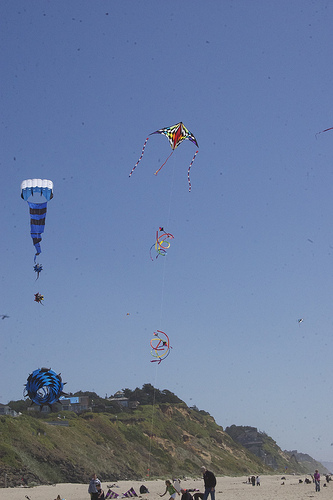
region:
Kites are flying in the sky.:
[31, 131, 204, 342]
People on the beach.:
[135, 446, 328, 485]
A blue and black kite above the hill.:
[22, 358, 83, 408]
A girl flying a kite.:
[143, 472, 176, 493]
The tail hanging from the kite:
[157, 143, 170, 183]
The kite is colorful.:
[131, 313, 177, 364]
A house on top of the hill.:
[19, 388, 142, 423]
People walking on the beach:
[235, 458, 285, 495]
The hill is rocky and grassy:
[77, 419, 224, 461]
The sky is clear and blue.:
[47, 176, 288, 345]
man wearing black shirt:
[196, 464, 218, 498]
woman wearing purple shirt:
[307, 466, 328, 492]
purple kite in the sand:
[118, 483, 136, 497]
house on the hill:
[100, 386, 139, 417]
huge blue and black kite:
[19, 356, 81, 415]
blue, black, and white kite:
[15, 167, 57, 288]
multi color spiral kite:
[143, 214, 186, 281]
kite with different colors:
[121, 107, 214, 197]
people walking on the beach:
[244, 467, 266, 486]